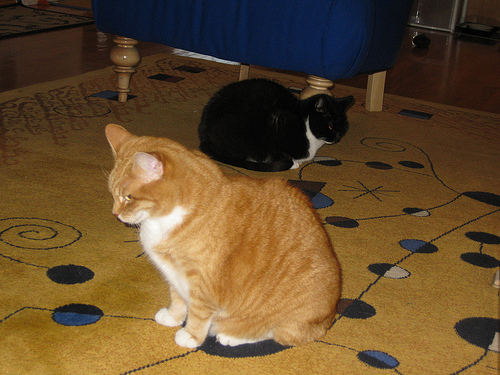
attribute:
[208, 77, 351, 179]
cat — black 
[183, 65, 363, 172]
cat — black 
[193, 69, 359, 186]
cat — black 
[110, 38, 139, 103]
leg — decorative, wooden, table 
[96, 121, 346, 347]
cat — yellow, white, tabby, brown, Tan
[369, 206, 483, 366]
carpet — yellow 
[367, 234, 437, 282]
patterns — white, black, blue 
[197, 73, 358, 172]
cat — black, white, house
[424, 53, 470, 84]
floors — shiny, hardwood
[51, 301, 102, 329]
circle — black, blue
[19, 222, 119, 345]
carpet — yellow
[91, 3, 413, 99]
cushion — blue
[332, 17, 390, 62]
cloth — blue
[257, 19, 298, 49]
cloth — blue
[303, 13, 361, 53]
cloth — blue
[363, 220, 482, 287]
pattern — dot 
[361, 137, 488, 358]
rug — brown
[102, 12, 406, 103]
furniture — dark blue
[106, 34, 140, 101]
leg — blonde, wooden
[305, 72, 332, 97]
leg — wooden, blonde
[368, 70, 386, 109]
leg — blonde, wooden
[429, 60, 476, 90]
flooring — hardwood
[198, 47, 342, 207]
cat — white , Black 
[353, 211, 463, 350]
rug — Tan , blue , black dots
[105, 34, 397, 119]
legs — Wooden 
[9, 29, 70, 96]
floors — Hardwood 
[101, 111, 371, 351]
cat — Black 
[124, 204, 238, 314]
chest — white 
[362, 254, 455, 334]
dot — Black, black swirl design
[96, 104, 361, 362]
cat — Tan ,  white chest, feet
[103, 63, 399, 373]
cat — lying down, sitting up